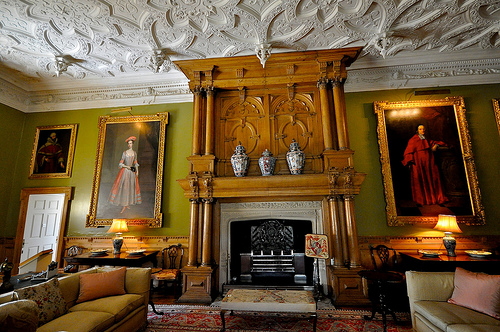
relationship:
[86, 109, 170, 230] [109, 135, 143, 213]
painting of woman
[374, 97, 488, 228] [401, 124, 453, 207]
painting of man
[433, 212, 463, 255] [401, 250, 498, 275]
lamp on table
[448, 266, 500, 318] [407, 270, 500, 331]
pillow on sofa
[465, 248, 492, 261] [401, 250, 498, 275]
plate on table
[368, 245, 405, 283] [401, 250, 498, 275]
chair beside table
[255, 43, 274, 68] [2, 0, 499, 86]
spire on ceiling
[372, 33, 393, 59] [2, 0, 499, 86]
spire on ceiling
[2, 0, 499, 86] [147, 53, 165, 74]
ceiling has a spire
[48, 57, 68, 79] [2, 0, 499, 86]
spire on ceiling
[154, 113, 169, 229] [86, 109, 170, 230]
frame of painting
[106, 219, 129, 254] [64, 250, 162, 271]
lamp on table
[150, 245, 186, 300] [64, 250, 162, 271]
chair at table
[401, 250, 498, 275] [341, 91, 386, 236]
table against wall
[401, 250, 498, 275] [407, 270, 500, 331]
table behind sofa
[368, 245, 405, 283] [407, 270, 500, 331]
chair behind sofa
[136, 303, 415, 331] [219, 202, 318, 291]
rug in front of fireplace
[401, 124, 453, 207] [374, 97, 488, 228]
man in painting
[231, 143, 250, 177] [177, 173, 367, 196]
vase on mantle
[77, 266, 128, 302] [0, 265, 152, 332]
pillow on sofa